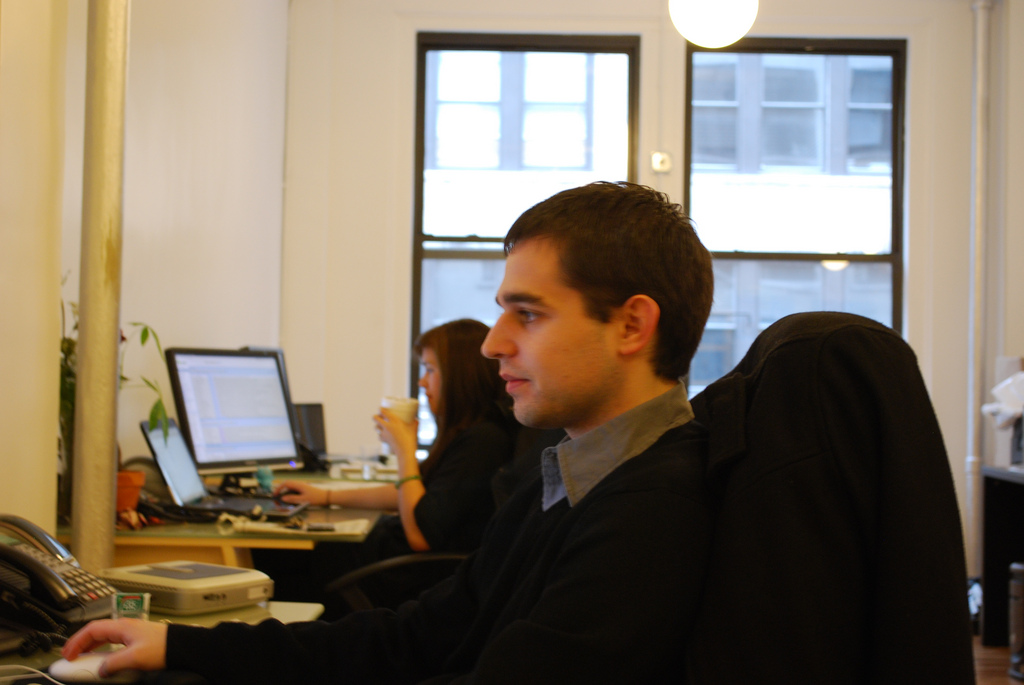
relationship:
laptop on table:
[138, 413, 309, 527] [115, 466, 388, 549]